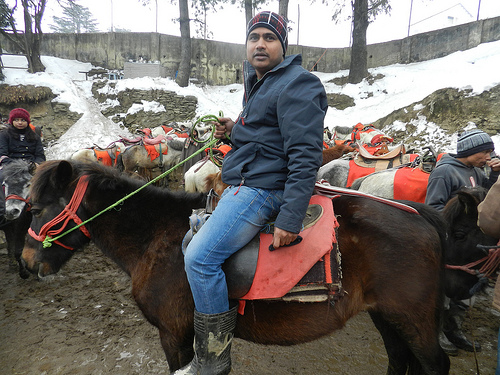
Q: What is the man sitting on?
A: A horse.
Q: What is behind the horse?
A: Snow.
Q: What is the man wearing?
A: Jeans.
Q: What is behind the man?
A: A wall.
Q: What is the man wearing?
A: A blue coat.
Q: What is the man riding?
A: A donkey.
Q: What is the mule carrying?
A: A man.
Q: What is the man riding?
A: A small horse.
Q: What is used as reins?
A: A green rope.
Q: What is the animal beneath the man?
A: A horse.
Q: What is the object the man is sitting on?
A: A saddle.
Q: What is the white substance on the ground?
A: Snow.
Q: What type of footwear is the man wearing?
A: Boots.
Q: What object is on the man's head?
A: A hat.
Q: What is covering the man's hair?
A: A hat.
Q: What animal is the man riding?
A: A horse.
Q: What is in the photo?
A: Pony.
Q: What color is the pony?
A: Brown.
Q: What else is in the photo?
A: Snow.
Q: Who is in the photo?
A: A man.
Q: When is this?
A: Daytime.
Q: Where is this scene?
A: Outside on a winter day.